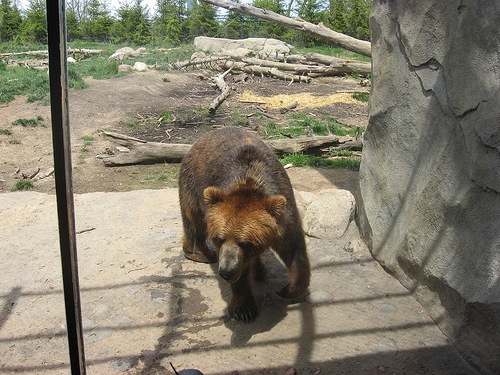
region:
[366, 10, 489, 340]
a light colored rock wall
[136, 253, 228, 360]
a water stain on the ground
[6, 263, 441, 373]
some shadow lines on the ground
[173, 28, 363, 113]
a pile of logs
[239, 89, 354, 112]
a pile of straw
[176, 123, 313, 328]
a small brown bear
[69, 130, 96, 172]
a few patches of grass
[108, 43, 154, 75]
a few large rocks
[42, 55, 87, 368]
a metal window pane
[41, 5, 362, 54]
a row of evergreens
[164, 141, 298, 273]
A brown bear in the zoo.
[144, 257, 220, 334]
Water on the ground.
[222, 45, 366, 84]
Tree trunks on the ground.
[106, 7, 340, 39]
Green trees in the background.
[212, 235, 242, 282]
The bear has a big nose.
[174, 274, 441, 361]
Reflection on the ground.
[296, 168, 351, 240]
A big rock on side of bear.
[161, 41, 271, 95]
Branches on the ground.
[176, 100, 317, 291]
The bear is brown.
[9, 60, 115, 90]
Green grass on the ground.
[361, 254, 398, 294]
part of a floor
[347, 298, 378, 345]
part of a floor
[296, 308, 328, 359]
part of a shade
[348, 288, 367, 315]
part of a floor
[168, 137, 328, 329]
a bear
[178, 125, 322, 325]
the bear is brown and black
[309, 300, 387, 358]
shadows on the ground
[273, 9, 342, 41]
a tree log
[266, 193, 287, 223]
the bears ear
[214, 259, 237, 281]
the bears nose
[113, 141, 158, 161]
a tree trunk on the ground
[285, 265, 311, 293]
front leg of the bear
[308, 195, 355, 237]
a rock on the ground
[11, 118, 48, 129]
patches of grass in the dirt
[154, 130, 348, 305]
bear on the ground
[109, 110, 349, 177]
log on the ground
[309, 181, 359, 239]
rock near the bear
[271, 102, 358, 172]
patch of grass under log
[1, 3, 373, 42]
row of trees in the back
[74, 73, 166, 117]
bare ground near the grass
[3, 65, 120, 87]
patches of ground in back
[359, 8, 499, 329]
stone surface on side of bear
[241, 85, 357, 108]
yellow pile on bare ground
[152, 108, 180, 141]
twigs on the ground